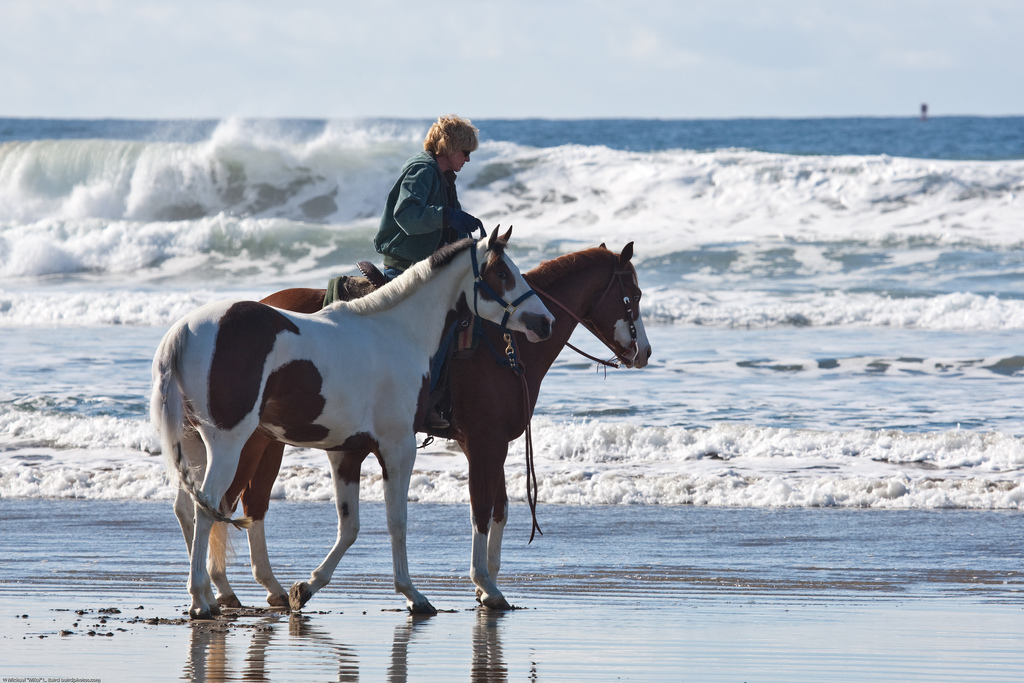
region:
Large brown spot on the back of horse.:
[207, 294, 285, 466]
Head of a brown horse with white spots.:
[550, 233, 667, 376]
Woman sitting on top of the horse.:
[365, 98, 508, 267]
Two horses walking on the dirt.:
[134, 212, 681, 604]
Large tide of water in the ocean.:
[102, 86, 889, 261]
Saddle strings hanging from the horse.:
[517, 376, 552, 554]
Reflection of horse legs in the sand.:
[166, 587, 537, 680]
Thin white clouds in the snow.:
[661, 48, 1000, 68]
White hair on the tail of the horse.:
[152, 309, 187, 455]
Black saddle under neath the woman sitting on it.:
[313, 262, 394, 305]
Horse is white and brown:
[147, 221, 565, 617]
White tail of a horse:
[150, 318, 250, 527]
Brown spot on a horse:
[207, 300, 299, 427]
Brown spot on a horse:
[260, 353, 325, 451]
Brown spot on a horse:
[326, 429, 388, 484]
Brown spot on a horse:
[516, 309, 552, 339]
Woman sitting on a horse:
[375, 113, 480, 285]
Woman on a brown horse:
[209, 239, 652, 620]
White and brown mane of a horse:
[327, 233, 479, 316]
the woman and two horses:
[155, 113, 652, 619]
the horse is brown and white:
[147, 224, 553, 620]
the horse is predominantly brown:
[209, 240, 652, 607]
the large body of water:
[2, 114, 1021, 507]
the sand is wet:
[0, 495, 1021, 679]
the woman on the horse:
[209, 114, 650, 609]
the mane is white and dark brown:
[327, 233, 476, 313]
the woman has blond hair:
[377, 117, 480, 431]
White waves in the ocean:
[1, 105, 1016, 527]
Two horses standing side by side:
[137, 209, 670, 627]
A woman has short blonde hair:
[412, 100, 486, 184]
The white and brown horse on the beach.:
[145, 225, 557, 636]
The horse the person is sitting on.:
[223, 234, 653, 637]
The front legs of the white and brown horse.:
[312, 435, 430, 619]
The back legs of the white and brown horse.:
[166, 417, 258, 624]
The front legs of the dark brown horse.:
[444, 427, 509, 602]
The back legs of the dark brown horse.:
[201, 430, 332, 589]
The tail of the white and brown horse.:
[150, 312, 258, 540]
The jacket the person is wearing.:
[365, 151, 473, 259]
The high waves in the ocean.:
[8, 142, 1021, 308]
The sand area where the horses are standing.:
[18, 582, 1022, 677]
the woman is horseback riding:
[162, 133, 722, 560]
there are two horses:
[153, 265, 476, 509]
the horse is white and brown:
[128, 180, 512, 529]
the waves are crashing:
[5, 142, 1015, 365]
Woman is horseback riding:
[253, 116, 659, 611]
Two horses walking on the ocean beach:
[156, 239, 653, 623]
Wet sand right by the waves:
[13, 581, 1019, 680]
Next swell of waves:
[5, 124, 1021, 502]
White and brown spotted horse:
[177, 230, 561, 616]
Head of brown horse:
[592, 244, 651, 366]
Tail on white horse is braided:
[155, 323, 247, 527]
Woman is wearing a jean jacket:
[381, 119, 479, 260]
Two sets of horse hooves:
[191, 576, 509, 618]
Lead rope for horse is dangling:
[510, 348, 549, 546]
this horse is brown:
[409, 208, 798, 481]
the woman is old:
[359, 105, 559, 254]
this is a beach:
[171, 79, 985, 671]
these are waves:
[56, 80, 960, 574]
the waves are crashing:
[141, 57, 841, 592]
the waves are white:
[76, 58, 666, 546]